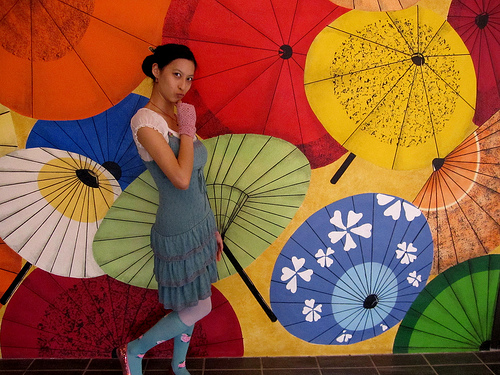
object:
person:
[115, 43, 225, 374]